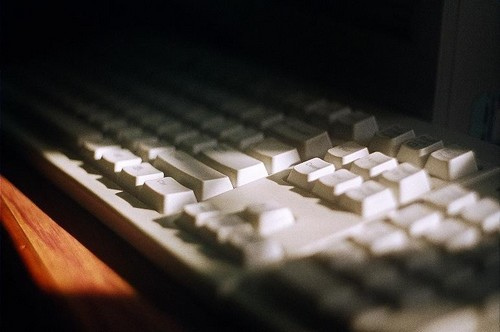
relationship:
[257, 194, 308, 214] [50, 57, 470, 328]
light shining on keyboard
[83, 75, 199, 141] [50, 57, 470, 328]
keys on top of keyboard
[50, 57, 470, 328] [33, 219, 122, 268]
keyboard on top of table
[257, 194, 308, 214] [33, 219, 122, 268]
light shining on table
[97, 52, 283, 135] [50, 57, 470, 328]
shadows on top of keyboard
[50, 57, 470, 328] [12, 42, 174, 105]
keyboard in dark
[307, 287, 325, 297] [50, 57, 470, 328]
sunshine on keyboard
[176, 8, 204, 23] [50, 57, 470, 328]
shadow cast on keyboard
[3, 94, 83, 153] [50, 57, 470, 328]
space on top of keyboard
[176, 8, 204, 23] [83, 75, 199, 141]
shadow on top of keys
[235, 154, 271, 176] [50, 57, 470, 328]
button on top of keyboard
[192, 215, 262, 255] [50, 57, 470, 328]
arrows on top of keyboard